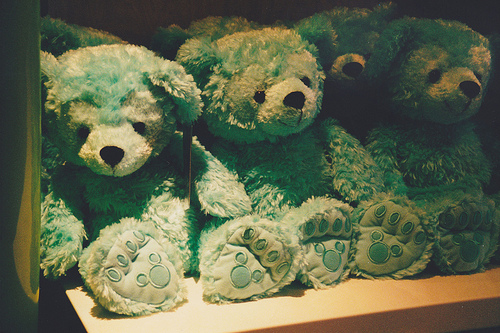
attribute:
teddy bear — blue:
[39, 43, 296, 311]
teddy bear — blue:
[175, 17, 436, 288]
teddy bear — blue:
[374, 13, 498, 272]